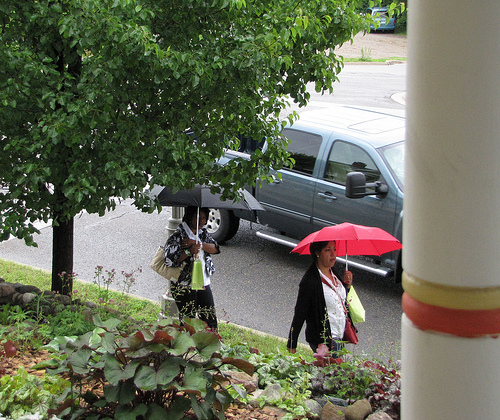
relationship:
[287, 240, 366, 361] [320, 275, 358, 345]
person with purse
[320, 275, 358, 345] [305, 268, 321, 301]
purse on shoulder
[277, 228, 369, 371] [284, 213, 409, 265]
person carrying red umbrella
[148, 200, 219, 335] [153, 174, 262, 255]
person carrying umbrella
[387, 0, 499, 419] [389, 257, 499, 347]
pole on ring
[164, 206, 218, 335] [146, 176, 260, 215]
person with umbrella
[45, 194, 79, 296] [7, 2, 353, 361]
trunk of tree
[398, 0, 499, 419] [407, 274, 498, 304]
pole with stripe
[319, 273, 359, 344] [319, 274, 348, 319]
purse with strap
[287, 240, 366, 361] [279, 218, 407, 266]
person carrying umbrella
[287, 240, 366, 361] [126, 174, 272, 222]
person carrying umbrella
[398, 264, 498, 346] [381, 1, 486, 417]
stripe on post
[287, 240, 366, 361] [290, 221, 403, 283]
person holding red umbrella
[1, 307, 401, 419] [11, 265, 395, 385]
plants along pathway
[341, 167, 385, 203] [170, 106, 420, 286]
mirror on truck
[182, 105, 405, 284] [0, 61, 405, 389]
car parked on road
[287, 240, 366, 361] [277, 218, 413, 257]
person carrying umbrella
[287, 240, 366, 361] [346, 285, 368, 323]
person carrying bag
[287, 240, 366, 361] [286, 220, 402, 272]
person holding umbrella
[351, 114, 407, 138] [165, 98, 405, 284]
sunroof on truck